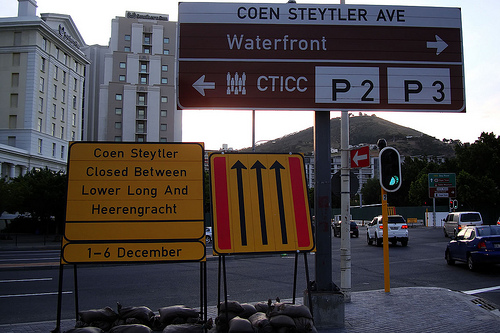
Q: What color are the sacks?
A: Brown.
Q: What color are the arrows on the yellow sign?
A: Black.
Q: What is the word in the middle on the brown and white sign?
A: Waterfront.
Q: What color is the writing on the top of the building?
A: Dark brown.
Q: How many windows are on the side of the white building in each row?
A: 4.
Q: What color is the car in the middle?
A: White.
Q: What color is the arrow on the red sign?
A: White.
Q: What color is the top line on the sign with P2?
A: White.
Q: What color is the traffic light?
A: Green.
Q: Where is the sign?
A: Waterfront.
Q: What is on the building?
A: Windows.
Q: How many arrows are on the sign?
A: Three.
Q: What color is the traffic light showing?
A: Green.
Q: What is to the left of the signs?
A: A building.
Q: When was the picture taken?
A: Day time.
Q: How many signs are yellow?
A: Two.